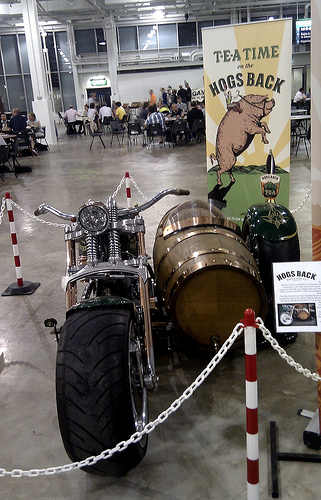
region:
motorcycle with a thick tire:
[26, 186, 187, 477]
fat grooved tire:
[51, 301, 163, 482]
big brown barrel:
[155, 199, 263, 352]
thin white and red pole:
[234, 309, 268, 496]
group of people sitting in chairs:
[61, 92, 204, 144]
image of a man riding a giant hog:
[209, 83, 281, 192]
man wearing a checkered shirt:
[143, 104, 164, 132]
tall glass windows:
[2, 22, 78, 126]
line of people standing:
[148, 77, 192, 106]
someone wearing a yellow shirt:
[113, 99, 126, 121]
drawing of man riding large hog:
[207, 90, 276, 189]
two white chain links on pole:
[2, 305, 315, 498]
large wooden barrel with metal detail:
[157, 199, 262, 370]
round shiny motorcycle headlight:
[71, 199, 110, 237]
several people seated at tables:
[51, 84, 203, 150]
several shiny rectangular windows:
[74, 20, 200, 59]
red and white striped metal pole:
[239, 305, 264, 499]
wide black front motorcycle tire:
[52, 294, 156, 497]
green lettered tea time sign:
[211, 42, 280, 64]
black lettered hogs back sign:
[205, 68, 285, 96]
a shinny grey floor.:
[179, 422, 236, 472]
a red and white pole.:
[0, 187, 44, 303]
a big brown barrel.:
[150, 190, 270, 351]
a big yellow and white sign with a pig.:
[179, 7, 311, 188]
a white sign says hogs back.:
[268, 256, 319, 339]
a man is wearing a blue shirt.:
[10, 116, 25, 126]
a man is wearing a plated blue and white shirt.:
[141, 112, 168, 125]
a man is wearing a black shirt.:
[182, 99, 212, 126]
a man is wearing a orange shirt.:
[146, 88, 160, 104]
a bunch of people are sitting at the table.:
[40, 57, 211, 167]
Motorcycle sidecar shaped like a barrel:
[152, 199, 264, 358]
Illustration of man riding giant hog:
[208, 90, 274, 185]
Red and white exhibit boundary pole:
[240, 307, 259, 497]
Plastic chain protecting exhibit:
[1, 321, 240, 483]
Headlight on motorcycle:
[74, 199, 112, 235]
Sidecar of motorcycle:
[160, 198, 301, 364]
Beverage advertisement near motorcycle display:
[199, 15, 293, 225]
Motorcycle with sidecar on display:
[34, 184, 302, 479]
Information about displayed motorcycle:
[274, 259, 319, 334]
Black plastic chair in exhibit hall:
[107, 119, 129, 148]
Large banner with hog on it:
[197, 16, 295, 229]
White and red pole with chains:
[235, 306, 262, 499]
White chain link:
[0, 319, 247, 480]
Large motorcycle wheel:
[53, 304, 157, 475]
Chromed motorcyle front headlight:
[75, 202, 112, 234]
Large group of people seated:
[61, 80, 206, 151]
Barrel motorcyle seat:
[150, 198, 272, 351]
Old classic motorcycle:
[34, 180, 307, 478]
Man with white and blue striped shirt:
[140, 102, 171, 145]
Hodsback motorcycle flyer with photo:
[273, 257, 320, 331]